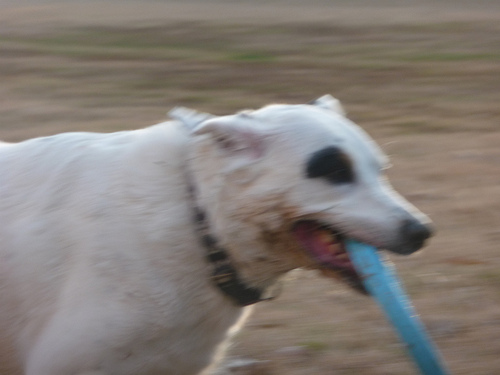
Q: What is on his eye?
A: Spot.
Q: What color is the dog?
A: White.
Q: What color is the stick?
A: Blue.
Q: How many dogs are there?
A: One.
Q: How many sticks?
A: One.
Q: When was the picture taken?
A: During the day.